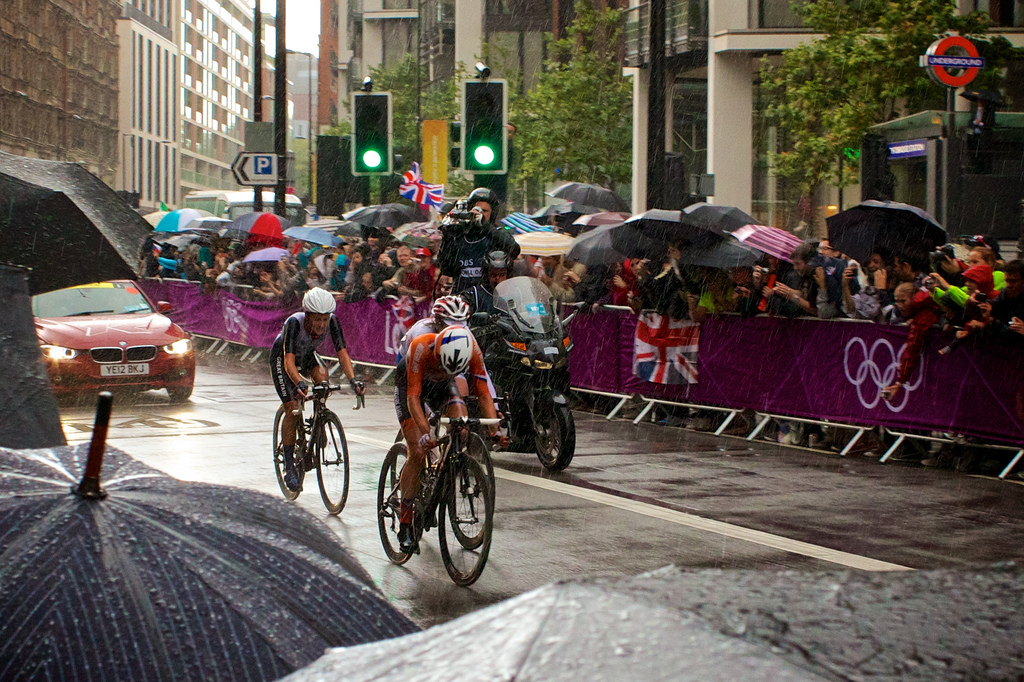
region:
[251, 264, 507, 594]
Bicycle racers on city street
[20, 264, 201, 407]
Red car following bicycle racers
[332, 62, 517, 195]
Stop lights with green lights on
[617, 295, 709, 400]
British flag banner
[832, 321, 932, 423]
Olympic rings symbol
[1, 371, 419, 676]
Black umbrella of spectator watching bicycle race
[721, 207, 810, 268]
Pink and white striped umbrella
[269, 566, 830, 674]
Gray umbrella of spectator watching race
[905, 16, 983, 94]
Subway sign above spectators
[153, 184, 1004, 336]
Spectators watching bicycle race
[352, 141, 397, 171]
green light on the traffic signal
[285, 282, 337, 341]
helmet on the head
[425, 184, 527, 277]
person filming the bikers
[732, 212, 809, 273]
striped umbrella over the person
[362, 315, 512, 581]
man riding a bike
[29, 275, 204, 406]
car on the road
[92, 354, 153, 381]
License plate on the car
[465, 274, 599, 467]
motorcycle on the road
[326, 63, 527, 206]
Traffic light on the pole is green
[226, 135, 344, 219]
Sign with an arrow pointing to the left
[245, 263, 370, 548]
Cyclist behind the other cyclists on the road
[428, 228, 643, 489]
Man on motorcycle to monitor the cyclists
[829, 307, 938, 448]
Olympic symbol on the side of the barrier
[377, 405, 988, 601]
White line in the center of the road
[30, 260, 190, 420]
Red car following behind the cyclists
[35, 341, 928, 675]
People holding up the umbrellas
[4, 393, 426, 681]
A black umbrella covered in rain drops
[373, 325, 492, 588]
A person riding a bike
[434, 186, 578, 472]
A person videotaping from a motorcycle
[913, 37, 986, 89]
A London Tube sign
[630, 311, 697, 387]
The Union Jack Flag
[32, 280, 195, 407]
A red car driving on the road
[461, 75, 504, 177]
A green light traffic signal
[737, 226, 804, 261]
A red umbrella in the crowd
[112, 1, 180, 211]
A striped building in the background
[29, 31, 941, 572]
this is a bike race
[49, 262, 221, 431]
the car is moving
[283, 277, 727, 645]
the bikes are moving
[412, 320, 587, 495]
the helmet is white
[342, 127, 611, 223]
the traffic lights are green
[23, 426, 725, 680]
these are umbrellas